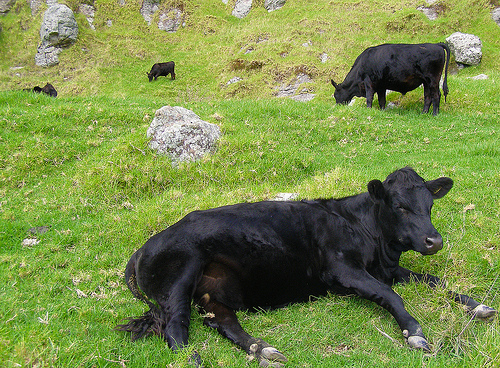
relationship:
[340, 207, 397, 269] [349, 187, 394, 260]
wrinkles on neck